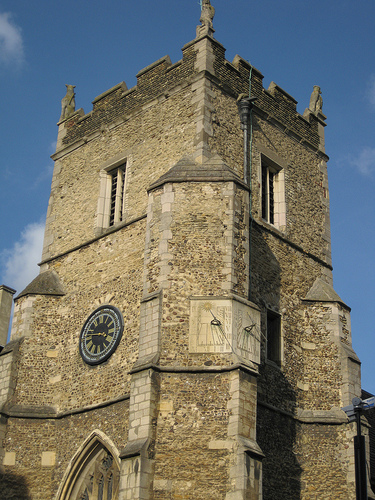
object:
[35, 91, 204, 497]
wall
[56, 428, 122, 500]
archway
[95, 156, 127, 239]
window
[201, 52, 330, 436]
side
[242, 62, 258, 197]
gutter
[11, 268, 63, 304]
roof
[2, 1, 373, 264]
sky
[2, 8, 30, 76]
cloud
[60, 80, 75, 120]
statue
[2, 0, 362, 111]
sunlight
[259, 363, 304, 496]
shadow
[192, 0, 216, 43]
statue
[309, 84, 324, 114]
statue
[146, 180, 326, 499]
wall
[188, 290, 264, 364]
scene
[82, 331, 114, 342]
time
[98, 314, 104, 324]
numbers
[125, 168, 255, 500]
corner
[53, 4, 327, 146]
rooff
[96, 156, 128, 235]
rectangles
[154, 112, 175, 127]
brick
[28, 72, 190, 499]
side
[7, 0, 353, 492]
tower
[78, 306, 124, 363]
clock